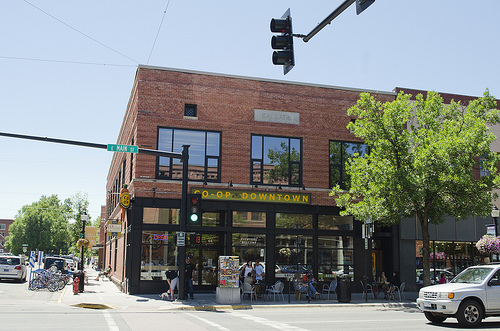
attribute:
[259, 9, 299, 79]
light — black, for traffic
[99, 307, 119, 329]
line — White 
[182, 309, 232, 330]
line — White 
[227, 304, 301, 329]
line — White 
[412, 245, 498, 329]
vehicle — white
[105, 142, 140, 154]
sign — green and white, street's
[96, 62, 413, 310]
building — brick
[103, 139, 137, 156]
street sign — Green , white 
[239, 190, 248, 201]
d — yellow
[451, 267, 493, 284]
windshield — clear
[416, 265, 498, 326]
suv — white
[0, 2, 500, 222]
sky — blue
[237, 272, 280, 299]
table — chair, dining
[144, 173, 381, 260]
sign — green , yellow 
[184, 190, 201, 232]
light — green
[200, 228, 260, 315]
display — white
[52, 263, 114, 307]
hydrant — red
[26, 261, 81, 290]
bicycles — parked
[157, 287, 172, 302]
dog — white , small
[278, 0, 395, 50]
pole — black, metal 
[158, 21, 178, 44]
clouds — white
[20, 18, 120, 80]
sky — blue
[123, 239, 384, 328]
area — table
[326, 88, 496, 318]
tree — gray and green ,  large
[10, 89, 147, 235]
clouds — white  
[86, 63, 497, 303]
building — Large, brick 